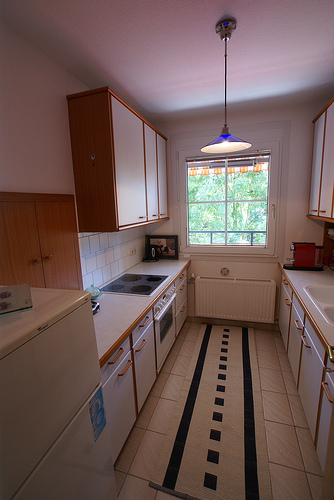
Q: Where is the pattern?
A: On rug.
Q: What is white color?
A: Freezer.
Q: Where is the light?
A: Ceiling.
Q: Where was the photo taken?
A: Kitchen.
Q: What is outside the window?
A: Trees.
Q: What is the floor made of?
A: Tiles.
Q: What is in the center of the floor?
A: Rug.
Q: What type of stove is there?
A: Electric.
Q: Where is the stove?
A: Between cabinets.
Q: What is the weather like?
A: Sunny.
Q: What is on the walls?
A: Cabinets.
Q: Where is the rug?
A: The floor.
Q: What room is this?
A: Kitchen.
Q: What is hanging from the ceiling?
A: Light.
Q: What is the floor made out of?
A: Tile.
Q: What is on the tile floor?
A: Rug.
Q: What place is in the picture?
A: A kitchen.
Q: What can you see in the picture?
A: A sink and an oven.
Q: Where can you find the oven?
A: On the left side by the wall.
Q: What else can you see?
A: Cabinets and window.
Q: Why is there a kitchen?
A: A place for cooking.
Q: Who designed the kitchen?
A: An architect.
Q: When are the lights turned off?
A: During night time.